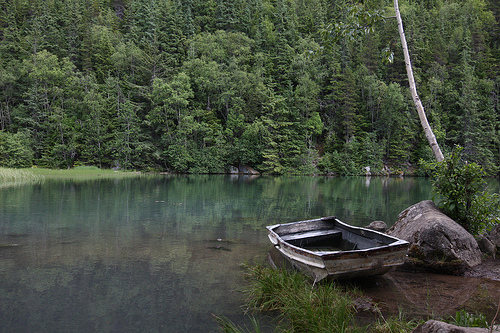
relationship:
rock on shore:
[394, 200, 486, 277] [285, 256, 493, 320]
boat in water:
[266, 213, 411, 284] [0, 168, 499, 330]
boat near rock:
[266, 213, 411, 284] [394, 200, 486, 277]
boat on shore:
[266, 213, 411, 284] [285, 256, 493, 320]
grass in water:
[238, 259, 371, 331] [0, 168, 499, 330]